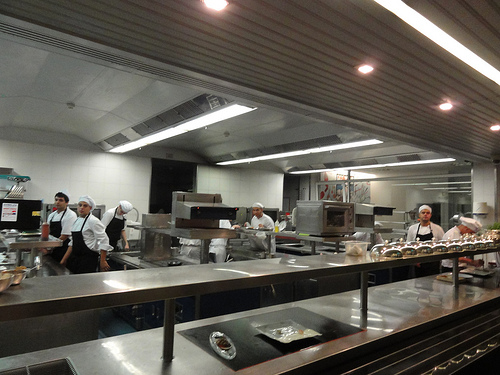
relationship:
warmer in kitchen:
[166, 181, 238, 233] [6, 3, 499, 367]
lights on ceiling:
[101, 101, 253, 156] [34, 77, 344, 174]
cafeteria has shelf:
[10, 4, 499, 374] [117, 243, 494, 364]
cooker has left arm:
[66, 191, 125, 272] [93, 222, 115, 270]